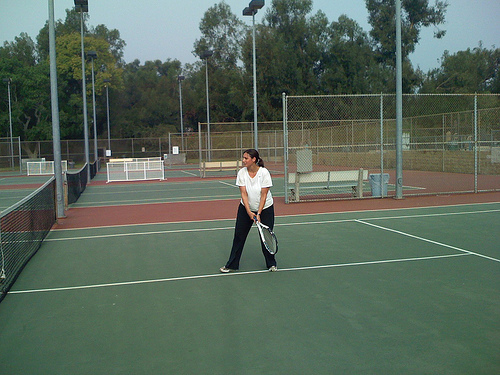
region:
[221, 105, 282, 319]
a woman playing tennis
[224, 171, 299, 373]
a woman playing tennis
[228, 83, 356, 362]
a woman playing tennis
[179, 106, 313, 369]
a woman playing tennis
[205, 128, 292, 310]
woman standing on a tennis court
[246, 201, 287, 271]
black and white tennis racket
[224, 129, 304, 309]
woman wearing black pants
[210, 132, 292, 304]
woman wearing a white t-shirt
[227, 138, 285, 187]
woman with black hair in a ponytail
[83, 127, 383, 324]
woman standing on a green tennis court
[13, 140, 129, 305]
nets stretched across tennis courts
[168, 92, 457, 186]
silver metal fencing on a tennis court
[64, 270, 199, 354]
green tennis court with a white stripe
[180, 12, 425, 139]
trees behind a tennis court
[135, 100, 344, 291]
A woman on a tennis court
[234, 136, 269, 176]
A woman with a pony tail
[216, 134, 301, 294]
A woman holding a tennis racket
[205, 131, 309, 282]
A woman wearing a white shirt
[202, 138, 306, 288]
A woman wearing black pants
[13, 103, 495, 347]
Four tennis courts in a row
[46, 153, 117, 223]
Nets on a tennis court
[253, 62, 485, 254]
Fencing on a tennis court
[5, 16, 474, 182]
Trees beyond the tennis courts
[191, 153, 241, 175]
A bench near a tennis court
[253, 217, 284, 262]
black and white tennis racket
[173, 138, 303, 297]
a woman getting ready to serve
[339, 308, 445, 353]
a flat green tennis court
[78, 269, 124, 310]
a white painted line on a tennis court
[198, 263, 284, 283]
black and white tennis shoes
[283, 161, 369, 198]
the back of a white bench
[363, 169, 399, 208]
a gray plastic trash can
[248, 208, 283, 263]
a black and white tennis racket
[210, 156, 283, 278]
a woman wearing a white shirt and black pants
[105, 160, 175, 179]
a partial white fence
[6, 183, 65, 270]
a black and white tennis net